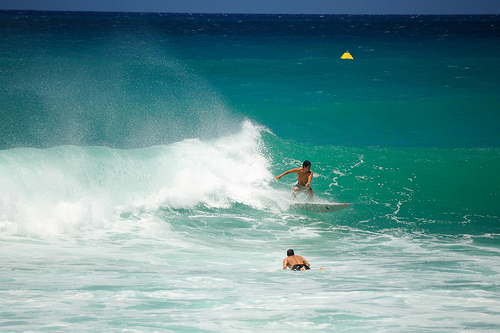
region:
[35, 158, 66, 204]
white wave in water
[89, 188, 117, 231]
white wave in water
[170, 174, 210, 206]
white wave in water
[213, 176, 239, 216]
white wave in water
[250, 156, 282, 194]
white wave in water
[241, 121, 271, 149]
white wave in water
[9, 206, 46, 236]
white wave in water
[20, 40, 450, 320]
The people are out in the ocean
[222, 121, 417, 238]
A person is on a surfboard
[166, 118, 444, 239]
A person is on an ocean wave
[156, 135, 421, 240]
A person is getting very wet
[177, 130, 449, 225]
A person is not wearing a shirt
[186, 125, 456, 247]
A person is out in the sunshine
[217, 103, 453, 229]
A person is getting good exercise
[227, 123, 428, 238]
A person is out in the daytime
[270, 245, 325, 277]
the man in the ocean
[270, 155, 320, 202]
the man in the ocean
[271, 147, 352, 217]
the man on the surfboard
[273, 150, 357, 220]
the man is surfing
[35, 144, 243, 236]
the wave is crashing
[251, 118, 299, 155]
the crest of the wave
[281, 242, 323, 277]
the man is wet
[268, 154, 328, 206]
the man is wet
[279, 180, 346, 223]
the surfboard is white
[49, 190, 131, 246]
the wave is splashing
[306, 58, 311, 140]
Mac laptop on top of the desk.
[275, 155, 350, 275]
two surfers riding the ocean waves.